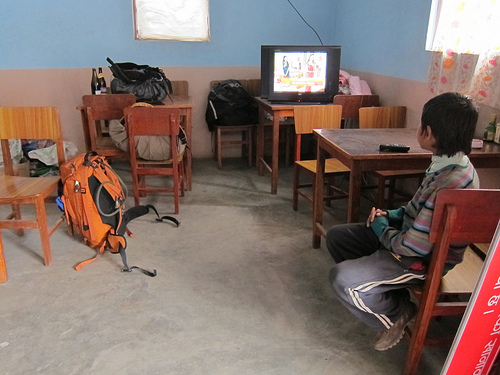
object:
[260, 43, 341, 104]
tv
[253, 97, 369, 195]
table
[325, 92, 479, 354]
boy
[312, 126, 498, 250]
table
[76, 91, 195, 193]
table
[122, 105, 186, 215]
chair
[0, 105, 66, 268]
chair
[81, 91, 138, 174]
chair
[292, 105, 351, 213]
chair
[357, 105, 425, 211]
chair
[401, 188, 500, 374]
chair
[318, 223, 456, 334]
sweatpants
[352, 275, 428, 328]
stipes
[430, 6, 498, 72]
light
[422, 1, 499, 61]
window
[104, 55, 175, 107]
backpack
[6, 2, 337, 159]
wall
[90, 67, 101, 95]
beer bottles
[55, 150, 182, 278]
backpack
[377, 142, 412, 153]
remote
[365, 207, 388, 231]
together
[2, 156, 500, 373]
floor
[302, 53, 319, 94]
women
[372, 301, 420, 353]
shoes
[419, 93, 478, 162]
hair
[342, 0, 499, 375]
side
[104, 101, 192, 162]
sack